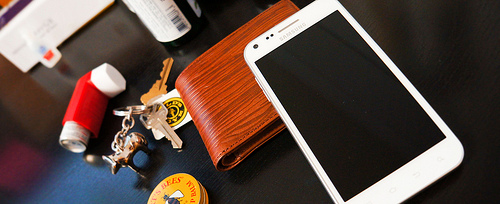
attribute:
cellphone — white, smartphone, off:
[244, 2, 464, 204]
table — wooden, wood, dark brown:
[0, 2, 499, 204]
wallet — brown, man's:
[175, 2, 300, 171]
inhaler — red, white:
[57, 63, 127, 155]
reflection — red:
[1, 136, 46, 199]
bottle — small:
[18, 28, 61, 70]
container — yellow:
[143, 172, 217, 202]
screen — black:
[254, 9, 447, 201]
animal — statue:
[99, 131, 152, 180]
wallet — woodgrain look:
[161, 31, 275, 160]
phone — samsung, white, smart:
[228, 19, 466, 195]